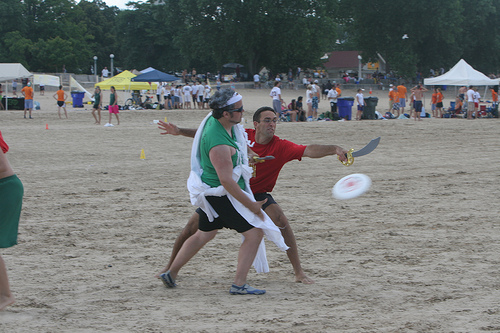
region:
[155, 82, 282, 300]
man in green shirt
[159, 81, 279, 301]
man in green shirt and black shorts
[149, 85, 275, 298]
man with toilet paper wrapped around his body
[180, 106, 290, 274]
toilet paper wrapped around the mans body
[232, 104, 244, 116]
glasses the man in the green shirt is wearing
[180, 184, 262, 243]
black shorts the man in the green shirt is wearing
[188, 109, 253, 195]
green shirt the man in the green shirt and black shorts is wearing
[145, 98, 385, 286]
man in red shirt and black shorts holding a toy knife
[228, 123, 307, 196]
red shirt the man in the red shirt and black shorts is wearing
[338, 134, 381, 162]
toy knife the man in the red shirt is holding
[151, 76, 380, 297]
a man is playing frisbee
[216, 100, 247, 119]
the man is wearing sunglasses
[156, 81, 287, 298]
white cloth is wrapped around the player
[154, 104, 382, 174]
a man has a fake sword in his hand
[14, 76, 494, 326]
people are on the sand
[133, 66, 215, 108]
a crowd of people are near a tent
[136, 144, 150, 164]
a yellow cone is on the sand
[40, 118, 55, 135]
an orange cone is in the sand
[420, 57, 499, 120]
people are under a white tent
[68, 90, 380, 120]
plastic refuse trash cans are on the sand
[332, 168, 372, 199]
a white Frisbee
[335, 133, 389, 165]
a man's sword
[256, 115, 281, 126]
a man's eyeglasses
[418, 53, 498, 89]
a large white tent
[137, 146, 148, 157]
a small yellow cone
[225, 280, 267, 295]
a man's blue shoe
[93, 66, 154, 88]
a large yellow tent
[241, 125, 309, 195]
part of a man's red shirt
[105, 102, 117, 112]
a woman's pink shorts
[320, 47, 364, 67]
the roof of a building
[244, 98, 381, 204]
man threw a frisbee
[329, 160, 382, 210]
frisbee is white and red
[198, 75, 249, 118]
man wearing a headband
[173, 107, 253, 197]
man's shirt is green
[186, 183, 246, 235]
man's shorts are black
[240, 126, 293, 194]
man's shirt is red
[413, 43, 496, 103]
the canopy is white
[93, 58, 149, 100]
the canopy is yellow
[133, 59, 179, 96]
the canopy is yellow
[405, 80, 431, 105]
person not wearing a shirt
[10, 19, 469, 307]
frisbee players on the beach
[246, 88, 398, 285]
this guy is weilding a sword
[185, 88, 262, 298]
this guy is wearing a toga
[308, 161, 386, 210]
the frisbee is white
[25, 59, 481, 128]
people in the background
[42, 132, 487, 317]
sandy beach area beneath people's feet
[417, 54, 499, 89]
a white tent top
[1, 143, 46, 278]
this person is wearing green shorts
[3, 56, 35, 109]
some type of structure on the beach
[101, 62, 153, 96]
a yellow tent top